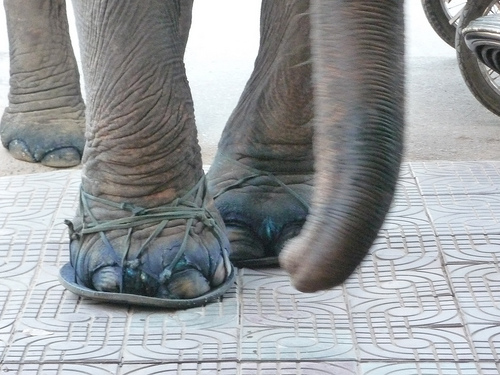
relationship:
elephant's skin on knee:
[70, 0, 199, 203] [85, 74, 200, 156]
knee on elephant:
[85, 74, 200, 156] [1, 4, 423, 314]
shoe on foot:
[58, 256, 234, 308] [67, 194, 232, 299]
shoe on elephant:
[26, 249, 302, 321] [42, 102, 292, 347]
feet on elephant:
[3, 96, 376, 317] [1, 4, 423, 314]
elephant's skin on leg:
[115, 58, 172, 198] [77, 10, 183, 63]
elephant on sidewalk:
[1, 4, 423, 314] [353, 290, 448, 372]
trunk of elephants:
[277, 2, 407, 295] [41, 60, 433, 289]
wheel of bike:
[453, 47, 493, 97] [434, 6, 498, 85]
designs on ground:
[13, 182, 467, 374] [304, 293, 396, 351]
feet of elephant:
[41, 204, 299, 309] [75, 46, 293, 280]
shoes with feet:
[69, 218, 223, 325] [31, 139, 314, 331]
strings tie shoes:
[74, 192, 189, 245] [83, 187, 183, 235]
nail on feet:
[168, 275, 200, 295] [77, 51, 247, 292]